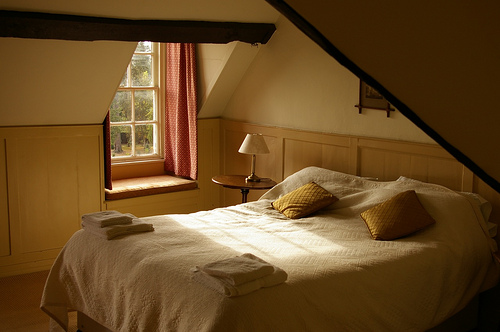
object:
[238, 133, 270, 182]
table lamp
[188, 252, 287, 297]
set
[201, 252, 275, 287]
folded towels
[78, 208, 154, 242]
set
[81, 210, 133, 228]
folded towels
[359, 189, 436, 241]
pillow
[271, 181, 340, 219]
pillow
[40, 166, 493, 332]
bedspread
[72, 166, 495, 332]
bed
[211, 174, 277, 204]
side table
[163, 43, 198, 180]
curtains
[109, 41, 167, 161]
window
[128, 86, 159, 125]
panes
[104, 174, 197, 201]
seat cushion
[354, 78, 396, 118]
picture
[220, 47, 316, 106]
wall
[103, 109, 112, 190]
curtain panel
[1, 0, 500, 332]
bedroom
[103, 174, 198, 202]
bench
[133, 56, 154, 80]
greenery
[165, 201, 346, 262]
sunlight